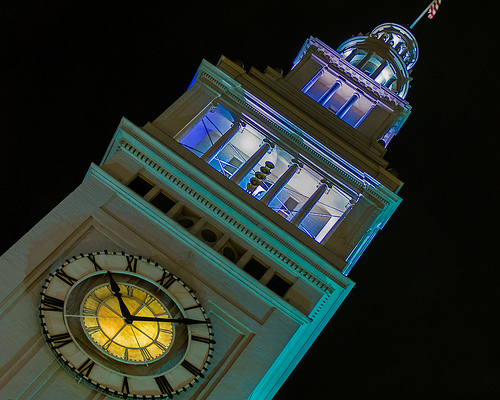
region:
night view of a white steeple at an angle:
[2, 5, 494, 395]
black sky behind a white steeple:
[3, 0, 496, 394]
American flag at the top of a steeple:
[400, 0, 445, 31]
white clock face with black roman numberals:
[35, 245, 215, 391]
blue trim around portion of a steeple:
[197, 54, 406, 280]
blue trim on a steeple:
[86, 118, 356, 395]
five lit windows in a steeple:
[176, 95, 357, 242]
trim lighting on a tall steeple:
[288, 15, 417, 147]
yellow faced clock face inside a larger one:
[76, 280, 175, 372]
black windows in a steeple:
[128, 163, 299, 302]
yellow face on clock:
[82, 258, 204, 388]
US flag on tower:
[381, 3, 443, 43]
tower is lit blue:
[125, 33, 430, 183]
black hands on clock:
[98, 247, 206, 358]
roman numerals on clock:
[51, 253, 202, 383]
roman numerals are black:
[42, 264, 216, 369]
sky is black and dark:
[382, 253, 493, 385]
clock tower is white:
[0, 198, 374, 389]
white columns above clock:
[210, 101, 374, 265]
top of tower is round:
[347, 5, 432, 99]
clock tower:
[4, 5, 469, 399]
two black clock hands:
[99, 256, 215, 355]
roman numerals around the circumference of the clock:
[29, 231, 239, 398]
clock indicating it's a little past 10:
[44, 226, 243, 398]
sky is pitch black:
[1, 0, 499, 397]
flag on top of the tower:
[407, 1, 447, 36]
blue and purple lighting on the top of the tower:
[160, 33, 417, 246]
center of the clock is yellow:
[75, 263, 181, 370]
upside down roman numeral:
[76, 351, 101, 379]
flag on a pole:
[405, 1, 444, 28]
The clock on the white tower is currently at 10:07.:
[37, 251, 217, 398]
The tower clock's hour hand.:
[105, 268, 132, 323]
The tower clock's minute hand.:
[125, 313, 208, 326]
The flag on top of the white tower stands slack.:
[410, 0, 441, 30]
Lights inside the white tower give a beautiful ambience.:
[180, 21, 420, 244]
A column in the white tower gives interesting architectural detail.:
[201, 113, 249, 170]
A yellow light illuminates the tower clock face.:
[78, 281, 176, 365]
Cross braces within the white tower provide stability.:
[174, 95, 354, 242]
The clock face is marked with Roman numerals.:
[37, 249, 213, 399]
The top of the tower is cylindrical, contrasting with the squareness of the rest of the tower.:
[334, 19, 421, 101]